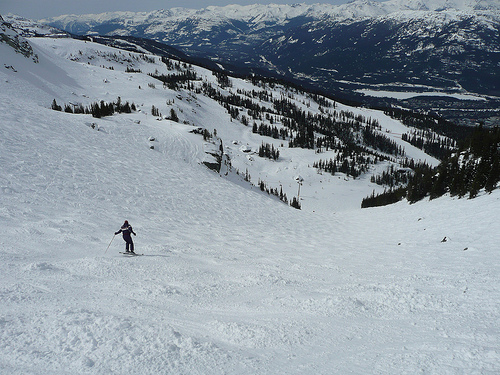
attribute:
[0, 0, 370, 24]
sky — blue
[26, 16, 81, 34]
clouds — white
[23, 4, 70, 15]
clouds — white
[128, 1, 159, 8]
sky — blue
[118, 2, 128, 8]
clouds — white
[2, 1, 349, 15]
sky — blue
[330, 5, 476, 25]
snow — white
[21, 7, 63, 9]
clouds — white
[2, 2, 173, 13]
sky — blue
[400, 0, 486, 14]
clouds — white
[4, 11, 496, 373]
snow — white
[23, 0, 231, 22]
sky — blue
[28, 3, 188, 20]
clouds — white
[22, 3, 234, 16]
sky — blue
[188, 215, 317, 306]
snow — white